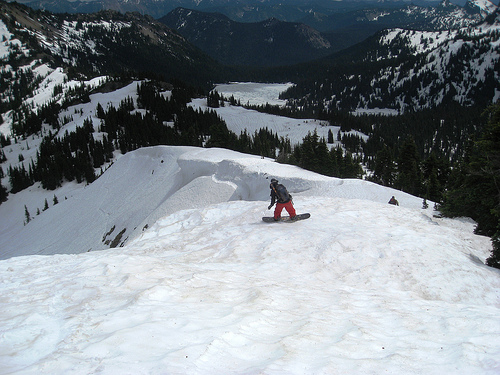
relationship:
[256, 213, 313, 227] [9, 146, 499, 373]
snowboard on snow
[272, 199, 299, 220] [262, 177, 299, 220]
pants on skier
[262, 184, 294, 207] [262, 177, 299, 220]
coat on skier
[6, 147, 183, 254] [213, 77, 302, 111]
slope snowy white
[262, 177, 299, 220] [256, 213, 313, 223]
skier on snowboard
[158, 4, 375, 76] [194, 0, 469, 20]
mountain in distance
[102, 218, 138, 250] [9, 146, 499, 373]
rocks through snow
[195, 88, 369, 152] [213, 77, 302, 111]
valley snowy white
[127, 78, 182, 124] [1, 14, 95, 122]
line of trees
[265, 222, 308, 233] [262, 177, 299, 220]
shadow of skier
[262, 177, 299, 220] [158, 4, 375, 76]
skier on mountain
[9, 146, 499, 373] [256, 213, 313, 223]
snow long snowboard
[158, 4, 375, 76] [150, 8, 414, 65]
mountain in background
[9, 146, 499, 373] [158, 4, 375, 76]
snow on mountain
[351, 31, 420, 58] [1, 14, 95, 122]
group of trees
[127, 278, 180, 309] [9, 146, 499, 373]
trail in snow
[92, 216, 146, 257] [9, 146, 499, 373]
rocks through snow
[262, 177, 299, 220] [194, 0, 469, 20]
skier in distance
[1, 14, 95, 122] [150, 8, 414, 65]
trees in background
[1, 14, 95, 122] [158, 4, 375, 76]
trees on mountain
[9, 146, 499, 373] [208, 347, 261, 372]
snow part collapsed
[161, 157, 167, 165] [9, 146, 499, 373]
grass through snow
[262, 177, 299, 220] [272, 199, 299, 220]
skier with pants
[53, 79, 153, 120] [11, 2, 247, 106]
snowy covered mountainside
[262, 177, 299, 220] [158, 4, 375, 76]
skier down mountain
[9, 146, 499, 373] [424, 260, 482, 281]
snow with streaks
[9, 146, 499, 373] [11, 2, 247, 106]
snow covered mountainside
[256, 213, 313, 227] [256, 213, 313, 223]
snowboard being snowboard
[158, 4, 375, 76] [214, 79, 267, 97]
mountain with ice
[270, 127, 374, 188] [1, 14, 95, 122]
evergreen tall trees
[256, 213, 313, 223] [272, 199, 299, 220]
snowboard red pants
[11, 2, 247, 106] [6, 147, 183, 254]
mountainside ski slope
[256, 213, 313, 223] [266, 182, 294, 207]
snowboard grey coat